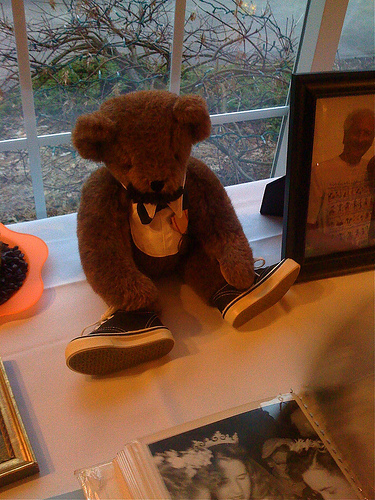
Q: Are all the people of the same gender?
A: No, they are both male and female.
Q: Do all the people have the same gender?
A: No, they are both male and female.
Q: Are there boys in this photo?
A: No, there are no boys.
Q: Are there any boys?
A: No, there are no boys.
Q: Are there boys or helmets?
A: No, there are no boys or helmets.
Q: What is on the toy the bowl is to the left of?
A: The shoes are on the teddy bear.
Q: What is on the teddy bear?
A: The shoes are on the teddy bear.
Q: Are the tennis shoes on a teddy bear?
A: Yes, the shoes are on a teddy bear.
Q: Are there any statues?
A: No, there are no statues.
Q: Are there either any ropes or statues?
A: No, there are no statues or ropes.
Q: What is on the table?
A: The picture frame is on the table.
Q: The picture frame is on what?
A: The picture frame is on the table.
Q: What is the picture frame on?
A: The picture frame is on the table.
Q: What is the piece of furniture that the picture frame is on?
A: The piece of furniture is a table.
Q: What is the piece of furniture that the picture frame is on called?
A: The piece of furniture is a table.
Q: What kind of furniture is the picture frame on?
A: The picture frame is on the table.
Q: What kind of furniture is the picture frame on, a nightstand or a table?
A: The picture frame is on a table.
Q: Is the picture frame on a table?
A: Yes, the picture frame is on a table.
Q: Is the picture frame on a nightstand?
A: No, the picture frame is on a table.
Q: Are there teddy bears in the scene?
A: Yes, there is a teddy bear.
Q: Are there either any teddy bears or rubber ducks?
A: Yes, there is a teddy bear.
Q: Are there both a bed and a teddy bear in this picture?
A: No, there is a teddy bear but no beds.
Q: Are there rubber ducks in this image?
A: No, there are no rubber ducks.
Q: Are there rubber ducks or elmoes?
A: No, there are no rubber ducks or elmoes.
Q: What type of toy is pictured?
A: The toy is a teddy bear.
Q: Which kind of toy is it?
A: The toy is a teddy bear.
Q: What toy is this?
A: This is a teddy bear.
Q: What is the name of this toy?
A: This is a teddy bear.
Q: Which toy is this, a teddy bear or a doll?
A: This is a teddy bear.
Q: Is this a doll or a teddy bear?
A: This is a teddy bear.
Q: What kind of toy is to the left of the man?
A: The toy is a teddy bear.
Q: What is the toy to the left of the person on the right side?
A: The toy is a teddy bear.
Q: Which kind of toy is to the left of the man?
A: The toy is a teddy bear.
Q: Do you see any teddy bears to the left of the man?
A: Yes, there is a teddy bear to the left of the man.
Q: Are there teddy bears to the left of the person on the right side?
A: Yes, there is a teddy bear to the left of the man.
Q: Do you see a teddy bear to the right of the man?
A: No, the teddy bear is to the left of the man.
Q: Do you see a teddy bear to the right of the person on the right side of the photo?
A: No, the teddy bear is to the left of the man.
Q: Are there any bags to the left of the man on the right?
A: No, there is a teddy bear to the left of the man.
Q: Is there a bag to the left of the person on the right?
A: No, there is a teddy bear to the left of the man.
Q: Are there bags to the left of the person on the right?
A: No, there is a teddy bear to the left of the man.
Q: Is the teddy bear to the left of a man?
A: Yes, the teddy bear is to the left of a man.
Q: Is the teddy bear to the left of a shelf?
A: No, the teddy bear is to the left of a man.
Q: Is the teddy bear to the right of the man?
A: No, the teddy bear is to the left of the man.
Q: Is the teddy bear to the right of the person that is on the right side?
A: No, the teddy bear is to the left of the man.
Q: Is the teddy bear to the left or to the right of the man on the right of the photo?
A: The teddy bear is to the left of the man.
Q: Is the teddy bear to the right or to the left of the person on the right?
A: The teddy bear is to the left of the man.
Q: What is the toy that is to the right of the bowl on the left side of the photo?
A: The toy is a teddy bear.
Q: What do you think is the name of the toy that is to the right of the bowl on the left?
A: The toy is a teddy bear.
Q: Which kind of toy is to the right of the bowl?
A: The toy is a teddy bear.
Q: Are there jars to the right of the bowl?
A: No, there is a teddy bear to the right of the bowl.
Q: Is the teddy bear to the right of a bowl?
A: Yes, the teddy bear is to the right of a bowl.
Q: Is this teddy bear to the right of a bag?
A: No, the teddy bear is to the right of a bowl.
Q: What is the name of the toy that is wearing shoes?
A: The toy is a teddy bear.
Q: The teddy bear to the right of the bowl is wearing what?
A: The teddy bear is wearing shoes.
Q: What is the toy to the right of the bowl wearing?
A: The teddy bear is wearing shoes.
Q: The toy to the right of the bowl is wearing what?
A: The teddy bear is wearing shoes.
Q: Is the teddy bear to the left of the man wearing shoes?
A: Yes, the teddy bear is wearing shoes.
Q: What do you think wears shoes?
A: The teddy bear wears shoes.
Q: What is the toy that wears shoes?
A: The toy is a teddy bear.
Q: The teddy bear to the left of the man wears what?
A: The teddy bear wears shoes.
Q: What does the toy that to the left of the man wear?
A: The teddy bear wears shoes.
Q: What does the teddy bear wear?
A: The teddy bear wears shoes.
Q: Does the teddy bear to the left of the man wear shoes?
A: Yes, the teddy bear wears shoes.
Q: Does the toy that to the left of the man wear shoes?
A: Yes, the teddy bear wears shoes.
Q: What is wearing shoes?
A: The teddy bear is wearing shoes.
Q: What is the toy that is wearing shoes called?
A: The toy is a teddy bear.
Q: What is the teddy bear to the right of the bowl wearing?
A: The teddy bear is wearing shoes.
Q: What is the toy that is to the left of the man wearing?
A: The teddy bear is wearing shoes.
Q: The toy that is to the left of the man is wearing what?
A: The teddy bear is wearing shoes.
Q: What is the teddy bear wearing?
A: The teddy bear is wearing shoes.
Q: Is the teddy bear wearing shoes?
A: Yes, the teddy bear is wearing shoes.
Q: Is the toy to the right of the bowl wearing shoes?
A: Yes, the teddy bear is wearing shoes.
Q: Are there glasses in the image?
A: No, there are no glasses.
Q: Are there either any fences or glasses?
A: No, there are no glasses or fences.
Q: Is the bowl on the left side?
A: Yes, the bowl is on the left of the image.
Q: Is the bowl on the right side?
A: No, the bowl is on the left of the image.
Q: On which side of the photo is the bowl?
A: The bowl is on the left of the image.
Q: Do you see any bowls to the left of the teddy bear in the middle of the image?
A: Yes, there is a bowl to the left of the teddy bear.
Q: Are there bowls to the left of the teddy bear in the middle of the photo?
A: Yes, there is a bowl to the left of the teddy bear.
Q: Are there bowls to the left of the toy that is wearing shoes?
A: Yes, there is a bowl to the left of the teddy bear.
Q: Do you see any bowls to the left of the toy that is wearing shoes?
A: Yes, there is a bowl to the left of the teddy bear.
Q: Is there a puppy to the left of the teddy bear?
A: No, there is a bowl to the left of the teddy bear.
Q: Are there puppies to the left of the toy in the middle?
A: No, there is a bowl to the left of the teddy bear.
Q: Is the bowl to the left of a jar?
A: No, the bowl is to the left of the teddy bear.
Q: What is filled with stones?
A: The bowl is filled with stones.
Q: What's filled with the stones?
A: The bowl is filled with stones.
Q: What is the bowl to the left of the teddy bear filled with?
A: The bowl is filled with stones.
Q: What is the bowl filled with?
A: The bowl is filled with stones.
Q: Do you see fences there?
A: No, there are no fences.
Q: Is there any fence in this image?
A: No, there are no fences.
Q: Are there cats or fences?
A: No, there are no fences or cats.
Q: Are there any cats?
A: No, there are no cats.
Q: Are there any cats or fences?
A: No, there are no cats or fences.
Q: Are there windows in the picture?
A: Yes, there is a window.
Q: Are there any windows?
A: Yes, there is a window.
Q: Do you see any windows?
A: Yes, there is a window.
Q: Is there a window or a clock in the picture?
A: Yes, there is a window.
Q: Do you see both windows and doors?
A: No, there is a window but no doors.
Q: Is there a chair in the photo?
A: No, there are no chairs.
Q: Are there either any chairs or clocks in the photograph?
A: No, there are no chairs or clocks.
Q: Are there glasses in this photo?
A: No, there are no glasses.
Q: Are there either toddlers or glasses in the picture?
A: No, there are no glasses or toddlers.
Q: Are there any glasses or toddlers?
A: No, there are no glasses or toddlers.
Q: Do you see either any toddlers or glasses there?
A: No, there are no glasses or toddlers.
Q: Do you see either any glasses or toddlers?
A: No, there are no glasses or toddlers.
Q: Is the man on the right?
A: Yes, the man is on the right of the image.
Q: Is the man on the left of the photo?
A: No, the man is on the right of the image.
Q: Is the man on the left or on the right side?
A: The man is on the right of the image.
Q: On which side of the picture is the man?
A: The man is on the right of the image.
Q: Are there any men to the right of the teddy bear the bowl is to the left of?
A: Yes, there is a man to the right of the teddy bear.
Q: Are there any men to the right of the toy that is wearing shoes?
A: Yes, there is a man to the right of the teddy bear.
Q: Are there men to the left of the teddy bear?
A: No, the man is to the right of the teddy bear.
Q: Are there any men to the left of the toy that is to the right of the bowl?
A: No, the man is to the right of the teddy bear.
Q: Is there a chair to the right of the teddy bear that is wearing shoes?
A: No, there is a man to the right of the teddy bear.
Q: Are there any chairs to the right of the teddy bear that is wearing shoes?
A: No, there is a man to the right of the teddy bear.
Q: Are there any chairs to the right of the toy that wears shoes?
A: No, there is a man to the right of the teddy bear.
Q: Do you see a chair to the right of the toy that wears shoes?
A: No, there is a man to the right of the teddy bear.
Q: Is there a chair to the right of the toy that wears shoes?
A: No, there is a man to the right of the teddy bear.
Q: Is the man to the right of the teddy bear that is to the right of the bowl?
A: Yes, the man is to the right of the teddy bear.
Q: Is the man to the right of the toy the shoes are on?
A: Yes, the man is to the right of the teddy bear.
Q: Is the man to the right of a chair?
A: No, the man is to the right of the teddy bear.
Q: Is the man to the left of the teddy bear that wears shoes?
A: No, the man is to the right of the teddy bear.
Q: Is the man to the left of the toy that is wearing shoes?
A: No, the man is to the right of the teddy bear.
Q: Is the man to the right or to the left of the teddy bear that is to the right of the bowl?
A: The man is to the right of the teddy bear.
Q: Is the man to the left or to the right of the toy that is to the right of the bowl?
A: The man is to the right of the teddy bear.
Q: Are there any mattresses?
A: No, there are no mattresses.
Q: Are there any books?
A: No, there are no books.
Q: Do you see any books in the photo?
A: No, there are no books.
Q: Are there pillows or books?
A: No, there are no books or pillows.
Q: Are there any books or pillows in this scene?
A: No, there are no books or pillows.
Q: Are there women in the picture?
A: Yes, there are women.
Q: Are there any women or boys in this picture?
A: Yes, there are women.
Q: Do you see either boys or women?
A: Yes, there are women.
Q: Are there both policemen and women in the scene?
A: No, there are women but no policemen.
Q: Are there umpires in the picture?
A: No, there are no umpires.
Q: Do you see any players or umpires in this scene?
A: No, there are no umpires or players.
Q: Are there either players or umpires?
A: No, there are no umpires or players.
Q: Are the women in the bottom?
A: Yes, the women are in the bottom of the image.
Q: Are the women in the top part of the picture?
A: No, the women are in the bottom of the image.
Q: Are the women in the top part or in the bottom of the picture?
A: The women are in the bottom of the image.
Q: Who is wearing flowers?
A: The women are wearing flowers.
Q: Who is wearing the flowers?
A: The women are wearing flowers.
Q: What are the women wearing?
A: The women are wearing flowers.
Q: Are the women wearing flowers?
A: Yes, the women are wearing flowers.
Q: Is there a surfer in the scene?
A: No, there are no surfers.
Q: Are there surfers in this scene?
A: No, there are no surfers.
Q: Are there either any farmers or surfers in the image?
A: No, there are no surfers or farmers.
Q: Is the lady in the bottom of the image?
A: Yes, the lady is in the bottom of the image.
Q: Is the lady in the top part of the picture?
A: No, the lady is in the bottom of the image.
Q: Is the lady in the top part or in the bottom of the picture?
A: The lady is in the bottom of the image.